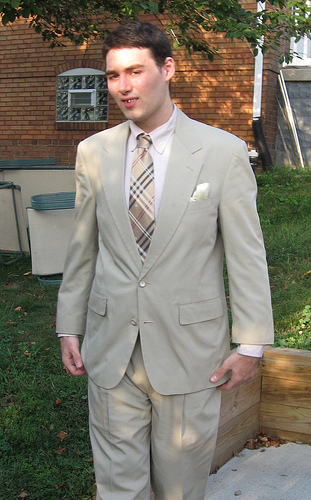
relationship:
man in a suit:
[56, 24, 275, 500] [56, 115, 273, 499]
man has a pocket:
[56, 24, 275, 500] [185, 182, 214, 244]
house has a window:
[1, 0, 76, 170] [55, 67, 108, 123]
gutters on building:
[252, 2, 275, 174] [1, 0, 76, 170]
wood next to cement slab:
[262, 346, 310, 443] [208, 474, 310, 499]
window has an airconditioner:
[52, 67, 108, 125] [66, 89, 96, 110]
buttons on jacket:
[139, 279, 147, 288] [55, 108, 276, 395]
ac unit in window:
[66, 89, 96, 110] [55, 67, 108, 123]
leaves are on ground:
[56, 429, 68, 443] [2, 277, 56, 499]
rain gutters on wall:
[252, 2, 275, 174] [176, 3, 288, 106]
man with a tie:
[56, 24, 275, 500] [128, 132, 156, 249]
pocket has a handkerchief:
[185, 182, 214, 244] [192, 180, 210, 198]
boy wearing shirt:
[56, 24, 275, 500] [128, 120, 175, 257]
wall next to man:
[262, 346, 310, 443] [56, 24, 275, 500]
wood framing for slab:
[262, 346, 310, 443] [208, 474, 310, 499]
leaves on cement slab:
[248, 434, 281, 451] [208, 474, 310, 499]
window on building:
[55, 67, 108, 123] [1, 0, 76, 170]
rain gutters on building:
[252, 2, 275, 174] [1, 0, 76, 170]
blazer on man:
[56, 115, 273, 499] [56, 24, 275, 500]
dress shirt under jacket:
[153, 107, 175, 164] [55, 108, 276, 395]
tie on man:
[128, 132, 156, 249] [56, 24, 275, 500]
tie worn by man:
[128, 132, 156, 249] [56, 24, 275, 500]